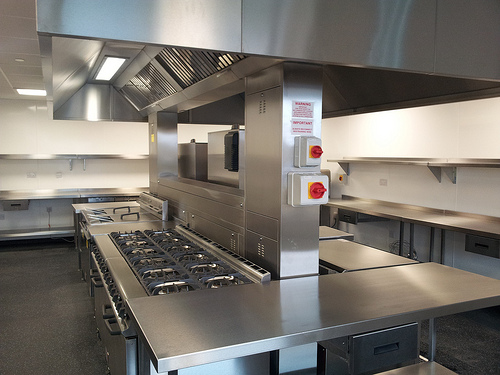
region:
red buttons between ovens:
[285, 134, 333, 216]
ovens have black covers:
[113, 197, 210, 298]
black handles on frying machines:
[85, 204, 155, 239]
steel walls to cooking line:
[110, 88, 331, 264]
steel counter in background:
[348, 173, 498, 244]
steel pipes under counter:
[396, 213, 445, 260]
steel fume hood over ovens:
[69, 26, 244, 114]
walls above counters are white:
[13, 118, 135, 159]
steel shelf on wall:
[12, 138, 132, 175]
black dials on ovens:
[77, 243, 142, 320]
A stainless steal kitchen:
[18, 74, 440, 341]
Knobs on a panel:
[285, 122, 340, 212]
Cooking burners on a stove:
[150, 245, 210, 296]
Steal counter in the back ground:
[7, 178, 135, 209]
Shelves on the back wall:
[310, 146, 490, 173]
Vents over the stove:
[132, 51, 229, 107]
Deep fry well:
[66, 190, 176, 227]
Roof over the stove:
[28, 18, 489, 121]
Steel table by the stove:
[132, 267, 487, 350]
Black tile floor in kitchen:
[12, 255, 67, 340]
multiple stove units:
[98, 215, 253, 344]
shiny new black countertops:
[177, 242, 470, 334]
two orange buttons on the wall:
[271, 133, 356, 233]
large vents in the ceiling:
[62, 15, 264, 147]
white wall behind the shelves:
[45, 137, 105, 187]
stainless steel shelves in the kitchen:
[22, 143, 127, 215]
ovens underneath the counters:
[66, 238, 142, 372]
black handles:
[95, 297, 134, 352]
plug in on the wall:
[375, 171, 397, 193]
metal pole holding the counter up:
[419, 290, 446, 357]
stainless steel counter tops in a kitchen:
[337, 183, 498, 282]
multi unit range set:
[104, 210, 248, 315]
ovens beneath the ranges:
[47, 212, 137, 363]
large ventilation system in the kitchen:
[98, 15, 266, 138]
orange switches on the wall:
[273, 145, 343, 221]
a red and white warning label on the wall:
[265, 90, 325, 163]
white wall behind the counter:
[15, 131, 122, 209]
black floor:
[18, 293, 54, 360]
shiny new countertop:
[290, 232, 445, 354]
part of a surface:
[286, 300, 318, 328]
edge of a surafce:
[316, 293, 371, 344]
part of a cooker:
[188, 236, 222, 271]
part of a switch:
[293, 161, 328, 201]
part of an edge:
[290, 198, 312, 248]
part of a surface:
[251, 288, 268, 304]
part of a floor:
[16, 306, 55, 363]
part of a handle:
[98, 316, 113, 340]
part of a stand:
[425, 322, 441, 344]